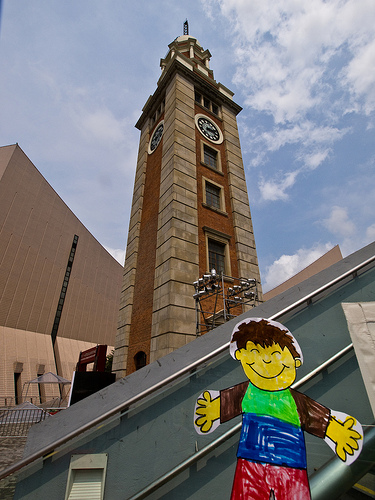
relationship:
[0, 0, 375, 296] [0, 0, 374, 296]
clouds in sky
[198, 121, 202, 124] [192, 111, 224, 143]
numeral on clock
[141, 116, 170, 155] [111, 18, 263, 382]
clock on clock tower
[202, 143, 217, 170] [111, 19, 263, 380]
window of a clock tower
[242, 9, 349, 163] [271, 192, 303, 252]
clouds in sky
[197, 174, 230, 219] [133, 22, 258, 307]
door in building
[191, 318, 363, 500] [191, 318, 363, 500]
figure of figure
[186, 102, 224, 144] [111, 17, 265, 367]
clock on tower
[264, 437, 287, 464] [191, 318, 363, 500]
marker on figure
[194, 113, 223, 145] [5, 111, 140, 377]
clock on building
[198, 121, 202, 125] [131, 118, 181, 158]
numeral on clock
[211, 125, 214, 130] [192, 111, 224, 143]
numeral on clock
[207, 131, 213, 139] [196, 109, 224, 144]
numeral on clock